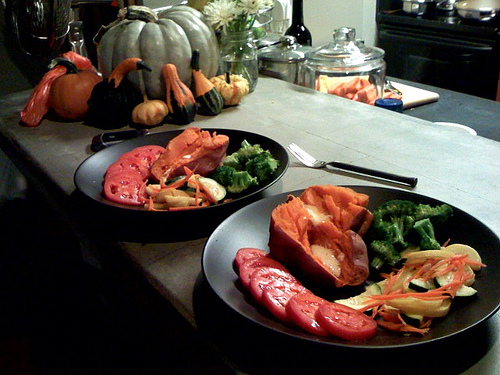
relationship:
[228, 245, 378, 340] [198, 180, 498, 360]
tomatoes on dish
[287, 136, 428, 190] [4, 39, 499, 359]
fork on table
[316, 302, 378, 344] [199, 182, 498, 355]
slice on plate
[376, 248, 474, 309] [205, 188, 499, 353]
vegetables in bowl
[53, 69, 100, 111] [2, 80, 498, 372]
pumpkin on table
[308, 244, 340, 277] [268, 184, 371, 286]
butter on sweet potato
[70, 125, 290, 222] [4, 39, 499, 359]
plate on table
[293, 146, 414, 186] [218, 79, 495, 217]
fork on table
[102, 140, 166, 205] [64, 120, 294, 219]
tomatoes on plate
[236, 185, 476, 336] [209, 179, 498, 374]
vegetables on plate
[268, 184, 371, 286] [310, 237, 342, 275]
sweet potato with butter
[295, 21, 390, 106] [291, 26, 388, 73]
glass jar with lid